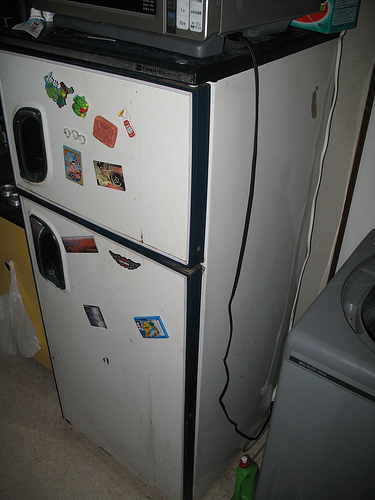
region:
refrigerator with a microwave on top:
[1, 0, 344, 498]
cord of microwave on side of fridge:
[212, 34, 262, 446]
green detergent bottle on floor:
[229, 451, 260, 498]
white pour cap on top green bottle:
[240, 454, 249, 463]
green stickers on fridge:
[40, 71, 91, 118]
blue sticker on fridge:
[130, 314, 170, 340]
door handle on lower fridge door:
[24, 211, 69, 291]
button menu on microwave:
[179, 1, 203, 33]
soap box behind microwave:
[286, 0, 359, 34]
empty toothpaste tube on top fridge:
[14, 15, 39, 38]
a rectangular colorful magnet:
[91, 160, 126, 192]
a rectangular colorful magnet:
[80, 302, 106, 330]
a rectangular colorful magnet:
[131, 315, 167, 340]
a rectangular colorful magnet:
[60, 234, 96, 252]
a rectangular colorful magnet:
[62, 142, 84, 186]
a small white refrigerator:
[0, 27, 335, 498]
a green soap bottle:
[233, 455, 259, 498]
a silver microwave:
[4, 1, 320, 55]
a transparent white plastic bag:
[0, 261, 41, 359]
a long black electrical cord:
[217, 36, 273, 442]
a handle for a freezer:
[10, 108, 49, 184]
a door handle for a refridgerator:
[23, 217, 62, 286]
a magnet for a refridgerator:
[81, 304, 108, 331]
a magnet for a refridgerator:
[133, 316, 169, 341]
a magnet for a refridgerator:
[57, 231, 99, 255]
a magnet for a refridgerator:
[107, 249, 142, 271]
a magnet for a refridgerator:
[91, 160, 129, 192]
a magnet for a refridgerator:
[61, 143, 85, 185]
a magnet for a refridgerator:
[89, 115, 121, 148]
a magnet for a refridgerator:
[43, 71, 71, 112]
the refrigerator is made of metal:
[8, 8, 316, 497]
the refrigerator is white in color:
[4, 2, 343, 495]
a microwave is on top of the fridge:
[18, 1, 281, 49]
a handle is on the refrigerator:
[30, 217, 67, 290]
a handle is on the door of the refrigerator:
[31, 215, 67, 292]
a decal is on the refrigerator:
[104, 249, 143, 275]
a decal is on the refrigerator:
[115, 103, 138, 142]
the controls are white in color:
[173, 1, 204, 36]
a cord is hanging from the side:
[214, 50, 259, 481]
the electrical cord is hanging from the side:
[219, 60, 250, 475]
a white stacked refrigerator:
[1, 25, 310, 497]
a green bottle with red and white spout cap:
[232, 455, 259, 499]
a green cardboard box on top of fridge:
[287, 0, 359, 32]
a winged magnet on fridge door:
[104, 248, 142, 271]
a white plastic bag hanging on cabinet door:
[1, 257, 43, 358]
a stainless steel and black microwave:
[14, 2, 321, 56]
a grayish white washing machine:
[251, 226, 374, 499]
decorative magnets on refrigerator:
[25, 71, 169, 340]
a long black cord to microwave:
[217, 34, 276, 447]